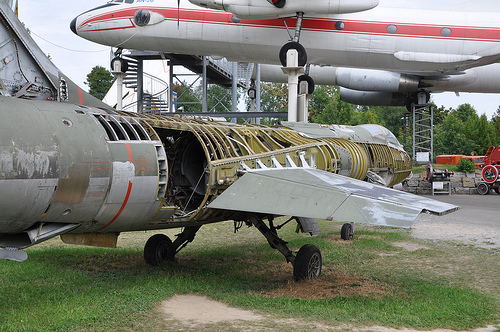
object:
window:
[441, 28, 451, 38]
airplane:
[68, 1, 499, 107]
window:
[388, 24, 396, 33]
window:
[334, 20, 347, 30]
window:
[231, 16, 238, 24]